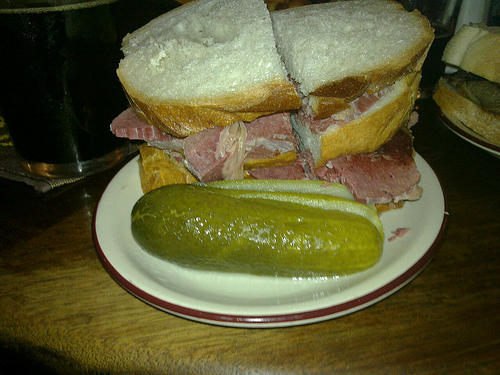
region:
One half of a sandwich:
[109, 1, 303, 194]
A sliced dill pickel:
[130, 178, 385, 278]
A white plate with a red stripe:
[89, 146, 451, 328]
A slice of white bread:
[118, 1, 299, 138]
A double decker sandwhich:
[110, 1, 433, 211]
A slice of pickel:
[129, 183, 384, 279]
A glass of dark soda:
[1, 0, 131, 180]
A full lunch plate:
[89, 1, 449, 328]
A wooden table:
[0, 1, 499, 374]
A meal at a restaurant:
[109, 1, 437, 273]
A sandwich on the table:
[12, 6, 496, 371]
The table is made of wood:
[391, 298, 487, 372]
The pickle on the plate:
[125, 174, 392, 269]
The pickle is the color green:
[128, 161, 388, 278]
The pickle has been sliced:
[117, 173, 391, 284]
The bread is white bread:
[149, 5, 423, 95]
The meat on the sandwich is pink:
[152, 120, 304, 178]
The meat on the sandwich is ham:
[131, 118, 322, 192]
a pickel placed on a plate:
[129, 187, 397, 279]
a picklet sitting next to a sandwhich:
[128, 182, 448, 299]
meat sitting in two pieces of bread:
[120, 114, 270, 206]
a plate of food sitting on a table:
[102, 102, 422, 372]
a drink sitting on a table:
[9, 7, 106, 217]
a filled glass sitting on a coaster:
[3, 0, 89, 206]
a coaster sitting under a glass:
[14, 151, 84, 208]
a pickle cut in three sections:
[164, 187, 396, 265]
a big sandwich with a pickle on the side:
[101, 10, 448, 325]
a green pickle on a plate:
[126, 171, 446, 278]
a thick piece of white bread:
[114, 9, 422, 124]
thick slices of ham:
[104, 105, 294, 172]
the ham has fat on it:
[189, 120, 266, 181]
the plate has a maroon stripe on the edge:
[108, 254, 428, 338]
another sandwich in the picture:
[433, 18, 496, 153]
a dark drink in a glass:
[4, 3, 136, 196]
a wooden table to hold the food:
[5, 217, 144, 367]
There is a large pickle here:
[213, 185, 283, 286]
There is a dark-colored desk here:
[433, 303, 448, 364]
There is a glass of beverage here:
[33, 91, 84, 202]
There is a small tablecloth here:
[23, 154, 64, 224]